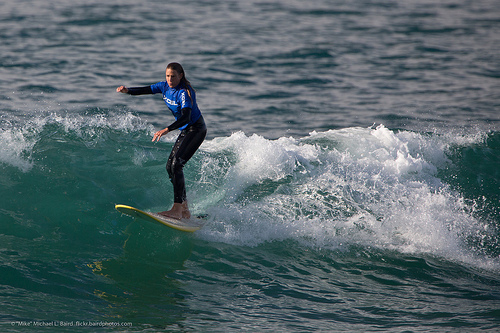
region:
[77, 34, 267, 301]
a woman is surfing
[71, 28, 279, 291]
the wetsuit is blue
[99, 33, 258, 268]
this person has long hair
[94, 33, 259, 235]
the sport of surfing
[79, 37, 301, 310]
the surfer catches a wave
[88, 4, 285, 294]
the water is green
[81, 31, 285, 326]
the surfboard is yellow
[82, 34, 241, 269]
the surfer is barefoot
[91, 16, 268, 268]
the surfer is balancing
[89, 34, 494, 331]
the surfer is riding a wave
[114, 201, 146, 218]
surfboard has yellow nose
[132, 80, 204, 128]
surfer wears blue, black, and white rash guard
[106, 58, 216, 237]
surfer stands atop surfboard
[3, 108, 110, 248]
wave is cresting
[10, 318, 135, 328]
copyright watermark for Michael Bard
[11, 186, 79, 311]
azure green water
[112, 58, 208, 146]
surfer balances by extending arms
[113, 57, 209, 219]
surfer is wet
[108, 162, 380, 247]
surfboard riding leaves wake in wave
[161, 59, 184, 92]
afternoon sun eastern shadow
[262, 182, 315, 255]
part of a splash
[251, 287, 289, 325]
part of some water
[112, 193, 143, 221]
edge of a board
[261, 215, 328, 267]
edge of a splash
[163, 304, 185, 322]
part of a shade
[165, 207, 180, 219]
edge of a leg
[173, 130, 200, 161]
part of a thigh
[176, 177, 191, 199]
edge of a leg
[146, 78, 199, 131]
a blue shirt on a surfer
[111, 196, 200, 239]
a yellow and white surfboard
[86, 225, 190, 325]
the reflection of a surfer and board on the water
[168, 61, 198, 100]
long wet hair on a surfer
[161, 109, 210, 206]
black pants on a person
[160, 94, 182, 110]
white letters on a shirt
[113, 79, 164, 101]
an arm held out for balance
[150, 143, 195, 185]
bent knees on a surfer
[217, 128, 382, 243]
white water crashing behind a surfer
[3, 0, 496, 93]
blue ocean water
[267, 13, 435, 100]
The water is blue.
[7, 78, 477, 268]
The wave is big.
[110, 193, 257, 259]
The board is yellow.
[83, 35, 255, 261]
The woman is surfing.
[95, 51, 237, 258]
She is wearing a wet suit.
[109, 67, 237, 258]
The wet suit is blue and black.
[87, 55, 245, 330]
She is wet.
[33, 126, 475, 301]
The wave is splashing.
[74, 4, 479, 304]
She is surfing in the ocean.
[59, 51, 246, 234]
She is standing on the board.